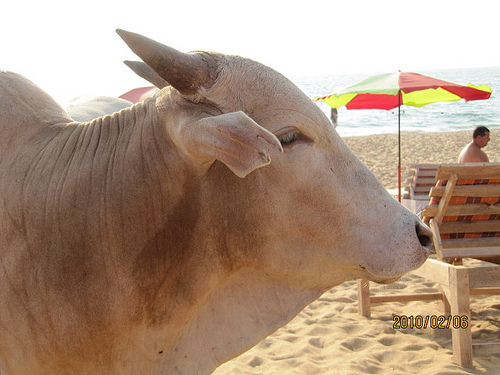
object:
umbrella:
[312, 69, 492, 111]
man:
[457, 126, 494, 168]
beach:
[211, 127, 499, 374]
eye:
[276, 123, 314, 153]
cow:
[0, 27, 435, 374]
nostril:
[415, 222, 434, 249]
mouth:
[358, 257, 427, 285]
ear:
[165, 108, 283, 180]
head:
[114, 28, 434, 302]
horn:
[115, 28, 217, 97]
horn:
[123, 59, 170, 91]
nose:
[408, 216, 435, 257]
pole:
[397, 93, 401, 202]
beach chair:
[384, 162, 438, 201]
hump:
[0, 67, 74, 147]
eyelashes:
[278, 130, 299, 142]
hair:
[473, 126, 489, 139]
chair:
[356, 164, 499, 366]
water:
[3, 66, 500, 140]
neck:
[51, 109, 334, 375]